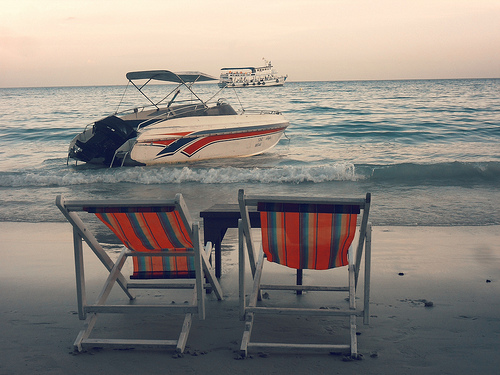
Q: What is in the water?
A: Boats.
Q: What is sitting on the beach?
A: Chairs.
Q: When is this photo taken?
A: Twilight.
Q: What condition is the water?
A: Choppy.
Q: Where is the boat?
A: On the shoreline.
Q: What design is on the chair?
A: Stripes.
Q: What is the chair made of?
A: Metal.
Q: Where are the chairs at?
A: The beach.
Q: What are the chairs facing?
A: The ocean.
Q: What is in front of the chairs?
A: Table.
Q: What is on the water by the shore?
A: A boat.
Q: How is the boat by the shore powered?
A: By an engine.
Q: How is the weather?
A: Overcast.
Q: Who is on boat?
A: Nobody?.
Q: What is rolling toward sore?
A: Wave.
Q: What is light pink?
A: Sky.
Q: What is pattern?
A: Stripes.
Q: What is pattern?
A: Stripes.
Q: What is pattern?
A: Stripes.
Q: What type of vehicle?
A: Boat.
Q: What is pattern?
A: Stripes.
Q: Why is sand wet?
A: Water.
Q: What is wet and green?
A: Water.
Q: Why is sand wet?
A: Water.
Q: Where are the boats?
A: On the water/.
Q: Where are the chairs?
A: On the beach.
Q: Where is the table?
A: In front of the chairs.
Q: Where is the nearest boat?
A: Anchored in shore.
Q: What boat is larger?
A: The further one.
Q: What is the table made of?
A: Wood.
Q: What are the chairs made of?
A: Wood.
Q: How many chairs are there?
A: Two.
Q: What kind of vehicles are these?
A: Boats.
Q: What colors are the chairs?
A: Orange, blue, and white.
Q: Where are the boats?
A: On the water.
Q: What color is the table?
A: Black.